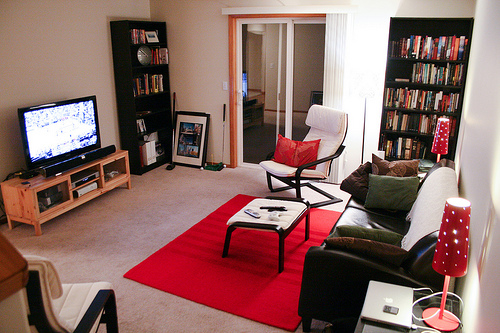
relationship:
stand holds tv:
[0, 146, 136, 237] [15, 93, 109, 170]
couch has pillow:
[296, 153, 465, 332] [362, 171, 417, 211]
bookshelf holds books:
[110, 16, 177, 175] [132, 72, 169, 95]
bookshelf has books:
[110, 16, 177, 175] [132, 72, 169, 95]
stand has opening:
[0, 146, 136, 237] [101, 156, 131, 182]